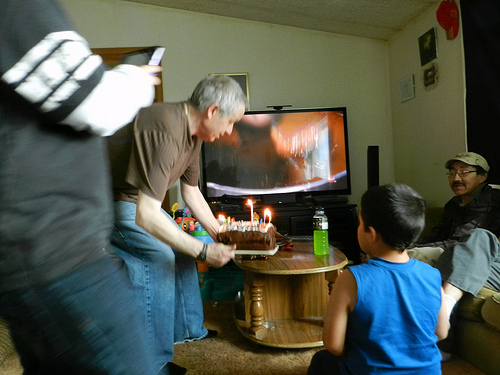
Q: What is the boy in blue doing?
A: Sitting.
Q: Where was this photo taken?
A: In a living room.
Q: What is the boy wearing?
A: A tanktop.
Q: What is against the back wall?
A: A TV.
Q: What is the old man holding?
A: A cake.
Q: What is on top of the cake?
A: Candles.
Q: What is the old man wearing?
A: Jeans.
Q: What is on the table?
A: A powerade.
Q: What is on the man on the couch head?
A: A hat.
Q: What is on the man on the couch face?
A: Eyeglasses.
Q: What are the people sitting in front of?
A: Television.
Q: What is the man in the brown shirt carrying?
A: Cake.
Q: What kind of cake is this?
A: Chocolate cake.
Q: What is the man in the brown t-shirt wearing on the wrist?
A: Watch.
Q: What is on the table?
A: Bottle with green drink.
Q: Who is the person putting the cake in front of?
A: Boy.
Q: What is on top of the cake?
A: Candles.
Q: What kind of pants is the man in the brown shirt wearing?
A: Blue jeans.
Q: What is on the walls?
A: Pictures.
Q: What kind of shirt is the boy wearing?
A: Sleeveless.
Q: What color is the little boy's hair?
A: Black.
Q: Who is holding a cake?
A: Man with grey hair.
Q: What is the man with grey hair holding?
A: A cake.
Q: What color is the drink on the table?
A: Green.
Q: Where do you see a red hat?
A: Hanging on the wall.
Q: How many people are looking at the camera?
A: 0.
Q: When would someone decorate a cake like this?
A: For a birthday.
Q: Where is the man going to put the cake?
A: On the table.